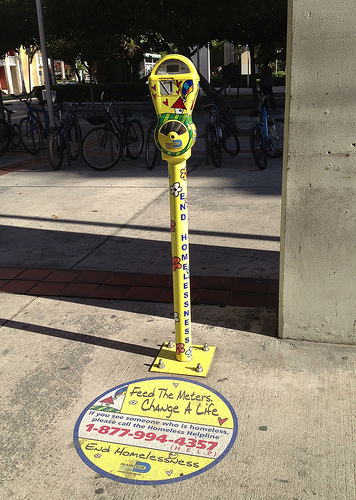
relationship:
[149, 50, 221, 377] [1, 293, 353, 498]
parking meter on street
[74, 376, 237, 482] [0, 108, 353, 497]
sign on sidewalk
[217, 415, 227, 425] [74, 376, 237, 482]
red heart on sign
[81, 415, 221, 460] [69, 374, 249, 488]
number on sign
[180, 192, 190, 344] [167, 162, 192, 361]
blue lettering on pole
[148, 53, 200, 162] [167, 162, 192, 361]
colored meter on pole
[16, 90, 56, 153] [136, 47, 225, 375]
bicycle behind parking meter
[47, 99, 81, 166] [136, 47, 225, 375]
bicycle behind parking meter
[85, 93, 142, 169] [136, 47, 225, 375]
bicycle behind parking meter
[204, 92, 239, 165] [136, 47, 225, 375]
bicycle behind parking meter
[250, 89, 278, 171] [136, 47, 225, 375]
bicycle behind parking meter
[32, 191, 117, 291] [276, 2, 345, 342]
shadow of pole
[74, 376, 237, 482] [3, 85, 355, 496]
sign on ground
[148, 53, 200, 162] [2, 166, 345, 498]
colored meter on pavement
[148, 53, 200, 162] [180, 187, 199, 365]
colored meter with blue lettering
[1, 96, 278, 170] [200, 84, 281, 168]
row of bicycles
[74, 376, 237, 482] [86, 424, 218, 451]
sign with number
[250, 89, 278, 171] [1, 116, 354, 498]
bicycle on side walk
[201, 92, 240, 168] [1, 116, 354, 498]
bicycle on side walk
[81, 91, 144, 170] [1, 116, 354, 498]
bicycle on side walk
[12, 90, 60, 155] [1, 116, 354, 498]
bicycle on side walk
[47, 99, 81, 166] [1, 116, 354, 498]
bicycle on side walk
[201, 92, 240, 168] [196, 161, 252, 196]
bicycle on sidewalk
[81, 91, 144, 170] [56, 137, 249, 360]
bicycle on sidewalk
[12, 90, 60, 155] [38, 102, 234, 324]
bicycle on sidewalk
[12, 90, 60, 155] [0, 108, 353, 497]
bicycle on sidewalk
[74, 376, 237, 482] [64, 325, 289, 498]
sign on sidewalk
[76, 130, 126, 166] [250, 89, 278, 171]
tire on bicycle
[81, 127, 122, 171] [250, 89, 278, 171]
tire on bicycle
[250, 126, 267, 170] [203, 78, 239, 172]
tire on bike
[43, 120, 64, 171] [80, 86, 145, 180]
tire on bike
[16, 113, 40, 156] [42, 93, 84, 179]
tire on bike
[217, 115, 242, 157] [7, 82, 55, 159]
tire on bike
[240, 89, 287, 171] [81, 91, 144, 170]
tire on bicycle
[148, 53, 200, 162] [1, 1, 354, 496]
colored meter in city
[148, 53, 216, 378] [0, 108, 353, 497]
parking meter on sidewalk